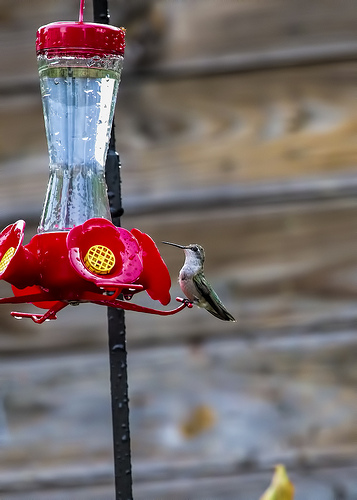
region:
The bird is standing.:
[165, 236, 240, 323]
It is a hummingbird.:
[153, 222, 240, 338]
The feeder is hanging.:
[29, 8, 179, 328]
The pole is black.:
[110, 314, 162, 458]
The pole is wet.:
[83, 334, 152, 495]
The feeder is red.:
[51, 235, 150, 277]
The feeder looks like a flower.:
[70, 216, 143, 311]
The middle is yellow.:
[88, 237, 122, 281]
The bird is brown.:
[158, 217, 246, 333]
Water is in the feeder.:
[32, 50, 117, 225]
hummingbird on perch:
[161, 230, 253, 329]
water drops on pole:
[106, 335, 137, 440]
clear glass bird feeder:
[37, 56, 127, 181]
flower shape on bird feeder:
[65, 217, 144, 291]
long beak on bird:
[155, 235, 188, 256]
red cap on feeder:
[40, 9, 137, 59]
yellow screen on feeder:
[82, 242, 119, 276]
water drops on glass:
[51, 68, 74, 93]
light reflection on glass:
[91, 73, 117, 165]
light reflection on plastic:
[11, 213, 27, 239]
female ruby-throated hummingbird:
[158, 233, 246, 328]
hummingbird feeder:
[0, 13, 199, 331]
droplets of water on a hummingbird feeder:
[30, 22, 132, 163]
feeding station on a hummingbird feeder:
[65, 214, 148, 300]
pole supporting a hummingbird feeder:
[103, 95, 131, 459]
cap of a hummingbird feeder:
[27, 15, 135, 59]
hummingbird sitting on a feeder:
[156, 232, 244, 328]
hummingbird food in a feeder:
[34, 63, 119, 231]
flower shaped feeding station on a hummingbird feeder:
[0, 218, 38, 299]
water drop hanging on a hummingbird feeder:
[121, 286, 138, 303]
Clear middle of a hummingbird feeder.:
[35, 51, 125, 231]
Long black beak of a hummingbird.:
[160, 240, 184, 250]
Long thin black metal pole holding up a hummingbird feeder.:
[89, 0, 134, 499]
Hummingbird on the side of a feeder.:
[160, 239, 235, 323]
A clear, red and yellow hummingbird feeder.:
[1, 0, 202, 323]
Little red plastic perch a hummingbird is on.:
[115, 296, 192, 315]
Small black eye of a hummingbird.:
[189, 245, 198, 252]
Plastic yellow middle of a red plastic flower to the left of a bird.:
[84, 244, 117, 273]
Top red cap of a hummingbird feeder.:
[31, 18, 128, 56]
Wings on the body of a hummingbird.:
[193, 271, 237, 323]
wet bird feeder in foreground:
[19, 33, 149, 427]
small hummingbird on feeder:
[151, 226, 265, 331]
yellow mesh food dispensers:
[71, 223, 136, 279]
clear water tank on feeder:
[35, 55, 123, 217]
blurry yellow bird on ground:
[251, 456, 311, 498]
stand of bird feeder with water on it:
[98, 325, 136, 492]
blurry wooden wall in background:
[152, 22, 349, 196]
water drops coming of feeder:
[16, 311, 75, 321]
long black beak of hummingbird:
[154, 234, 190, 249]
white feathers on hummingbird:
[178, 269, 207, 290]